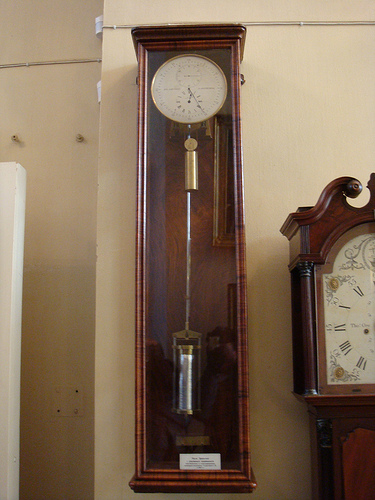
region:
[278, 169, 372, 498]
Dark brown wood clock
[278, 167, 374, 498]
Dark brown wood floor clock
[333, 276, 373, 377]
Roman numerals on a clock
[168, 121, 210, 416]
Chime hanging from a clock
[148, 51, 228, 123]
White analog clock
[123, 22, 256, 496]
Brown wood clock hanging on the wall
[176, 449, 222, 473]
White card with black writing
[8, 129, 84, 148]
two nails in the wall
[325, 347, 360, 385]
Decorative design on an analog clock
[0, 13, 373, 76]
Silver pipe secured to a wall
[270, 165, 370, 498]
a classic grandfather clock on display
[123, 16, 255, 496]
an unusual pendulum clock on the wall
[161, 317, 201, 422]
the pendulum swings back and forth to keep the clock running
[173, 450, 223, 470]
details about the clock on dispay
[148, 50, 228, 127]
the clock does not seem to tell conventional time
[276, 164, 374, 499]
classic grandfather clock in a beautifully carved case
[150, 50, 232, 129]
several different dials on this clock face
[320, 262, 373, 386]
classic grandfather clock simply has a 12 hour clock face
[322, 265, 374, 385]
classic grandfather clock uses Roman numerals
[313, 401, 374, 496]
classic grandfather clock has a door that hides pendulum from view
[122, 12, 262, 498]
a floor clock hang on the wall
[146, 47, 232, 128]
clock is color white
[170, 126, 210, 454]
the pendulum of a clock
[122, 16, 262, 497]
frame of clock is wood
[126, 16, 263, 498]
frame of clock is brown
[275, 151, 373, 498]
the clock is brown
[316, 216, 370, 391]
a white clock has roman numerals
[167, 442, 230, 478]
the label is color white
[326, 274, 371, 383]
roman numerals color black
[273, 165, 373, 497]
old clock in a brown box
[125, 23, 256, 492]
a clock on the wall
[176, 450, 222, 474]
a sign in the clock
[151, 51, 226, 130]
a white clock face in the clock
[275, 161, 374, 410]
a clock face on the right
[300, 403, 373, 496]
the stand of the clock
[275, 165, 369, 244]
wooden trim on top of the clock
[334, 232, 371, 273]
a design on the clock face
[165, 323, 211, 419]
the pendulum is swinging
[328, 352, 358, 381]
a gold mark on the clock face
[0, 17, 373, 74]
a cord along the wall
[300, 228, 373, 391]
THIS IS A CLOCK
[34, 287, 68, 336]
the wall is beige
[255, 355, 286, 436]
the wall is beige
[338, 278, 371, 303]
a number on the clock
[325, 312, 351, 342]
a number on the clock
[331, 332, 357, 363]
a number on the clock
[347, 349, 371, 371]
a number on the clock